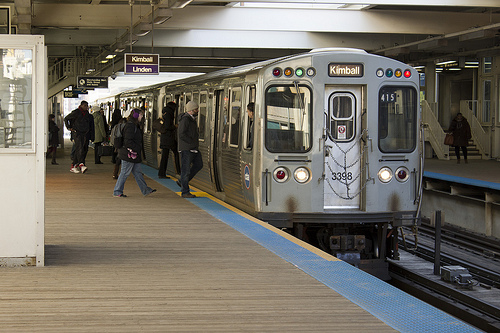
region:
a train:
[238, 60, 470, 257]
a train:
[245, 94, 373, 294]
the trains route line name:
[327, 62, 364, 77]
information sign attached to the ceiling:
[124, 53, 157, 75]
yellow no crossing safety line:
[204, 191, 336, 265]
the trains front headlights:
[294, 166, 309, 183]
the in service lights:
[271, 65, 315, 77]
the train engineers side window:
[245, 85, 257, 147]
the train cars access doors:
[322, 82, 367, 213]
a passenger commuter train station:
[0, 1, 498, 332]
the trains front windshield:
[264, 79, 314, 156]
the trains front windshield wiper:
[293, 76, 305, 149]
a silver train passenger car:
[160, 43, 428, 254]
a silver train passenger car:
[115, 75, 181, 160]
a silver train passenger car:
[83, 96, 120, 145]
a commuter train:
[80, 46, 445, 247]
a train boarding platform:
[28, 117, 473, 327]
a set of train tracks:
[348, 243, 498, 330]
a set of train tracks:
[392, 203, 499, 277]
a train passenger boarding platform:
[414, 149, 497, 189]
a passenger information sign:
[119, 51, 162, 79]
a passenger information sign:
[79, 76, 108, 88]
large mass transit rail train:
[165, 49, 430, 267]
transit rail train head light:
[293, 163, 314, 186]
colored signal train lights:
[270, 65, 317, 80]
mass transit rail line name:
[326, 61, 366, 78]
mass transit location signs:
[123, 48, 160, 77]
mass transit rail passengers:
[49, 100, 217, 200]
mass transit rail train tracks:
[415, 217, 499, 317]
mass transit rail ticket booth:
[0, 30, 60, 270]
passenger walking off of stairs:
[424, 94, 491, 164]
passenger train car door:
[321, 82, 368, 217]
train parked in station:
[125, 46, 420, 231]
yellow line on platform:
[237, 201, 317, 251]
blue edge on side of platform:
[365, 264, 430, 306]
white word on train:
[320, 57, 366, 84]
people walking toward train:
[88, 93, 217, 201]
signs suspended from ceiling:
[113, 42, 163, 83]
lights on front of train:
[288, 159, 398, 191]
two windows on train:
[263, 76, 415, 168]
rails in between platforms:
[414, 221, 463, 297]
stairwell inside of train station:
[431, 104, 488, 165]